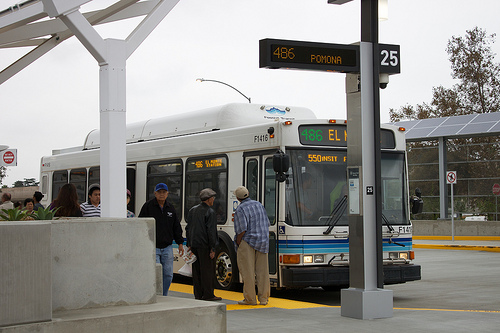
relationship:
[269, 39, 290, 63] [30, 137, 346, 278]
486 on bus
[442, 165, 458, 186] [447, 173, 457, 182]
sign for do not enter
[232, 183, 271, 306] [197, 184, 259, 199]
man are wearing hats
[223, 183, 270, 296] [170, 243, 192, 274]
man holding newspaper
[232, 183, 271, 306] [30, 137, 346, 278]
man are waiting to board bus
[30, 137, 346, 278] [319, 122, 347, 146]
bus traveling to el monte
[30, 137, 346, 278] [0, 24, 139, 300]
bus at station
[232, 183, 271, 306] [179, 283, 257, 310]
man are in line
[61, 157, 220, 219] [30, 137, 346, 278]
windows are on bus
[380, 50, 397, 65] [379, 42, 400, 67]
numbers are on signboard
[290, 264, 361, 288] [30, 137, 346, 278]
bumper in front of bus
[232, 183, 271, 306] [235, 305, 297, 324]
man are on sidewalk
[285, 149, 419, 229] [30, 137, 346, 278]
windshield attached to bus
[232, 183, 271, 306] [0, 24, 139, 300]
man are waiting at station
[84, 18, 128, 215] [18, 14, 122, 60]
support beam attached to roof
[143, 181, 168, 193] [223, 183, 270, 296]
hat on man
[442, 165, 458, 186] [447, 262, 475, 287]
sign for street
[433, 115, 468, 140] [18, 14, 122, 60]
solar panels are on roof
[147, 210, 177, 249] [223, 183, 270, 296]
jacket on man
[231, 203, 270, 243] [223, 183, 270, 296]
shirt on man